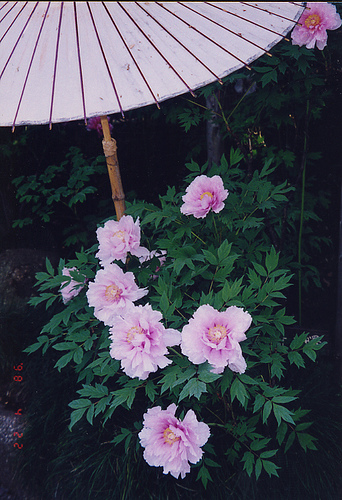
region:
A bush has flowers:
[49, 221, 336, 484]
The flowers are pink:
[54, 260, 292, 375]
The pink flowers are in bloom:
[55, 308, 321, 476]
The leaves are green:
[19, 319, 306, 496]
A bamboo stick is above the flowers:
[92, 120, 193, 233]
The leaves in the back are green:
[13, 140, 122, 217]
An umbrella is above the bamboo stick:
[0, 5, 215, 199]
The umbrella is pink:
[1, 359, 37, 451]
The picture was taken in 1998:
[7, 358, 48, 468]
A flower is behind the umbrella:
[255, 5, 340, 25]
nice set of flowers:
[39, 240, 253, 389]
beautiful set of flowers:
[39, 277, 285, 468]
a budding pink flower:
[128, 399, 215, 482]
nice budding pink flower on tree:
[129, 403, 213, 483]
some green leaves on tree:
[222, 393, 286, 473]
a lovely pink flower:
[134, 396, 212, 484]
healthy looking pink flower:
[127, 399, 213, 483]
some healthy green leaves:
[224, 379, 307, 447]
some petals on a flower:
[181, 416, 212, 459]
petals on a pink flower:
[140, 409, 163, 464]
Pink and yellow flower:
[172, 165, 241, 226]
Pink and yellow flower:
[187, 312, 248, 378]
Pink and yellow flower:
[117, 390, 216, 490]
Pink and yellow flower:
[96, 313, 179, 390]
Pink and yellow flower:
[86, 261, 150, 317]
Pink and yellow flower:
[90, 219, 170, 277]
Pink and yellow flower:
[136, 238, 169, 293]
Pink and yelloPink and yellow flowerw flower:
[50, 259, 106, 335]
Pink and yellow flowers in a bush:
[42, 181, 267, 454]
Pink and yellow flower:
[291, 6, 341, 66]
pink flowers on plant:
[51, 182, 270, 491]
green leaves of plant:
[40, 163, 317, 478]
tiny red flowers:
[8, 358, 27, 456]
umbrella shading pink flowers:
[6, 0, 318, 147]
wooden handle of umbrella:
[97, 125, 136, 217]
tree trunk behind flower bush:
[199, 92, 226, 162]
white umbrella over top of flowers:
[1, 3, 301, 123]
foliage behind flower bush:
[17, 136, 340, 267]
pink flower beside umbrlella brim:
[290, 5, 336, 46]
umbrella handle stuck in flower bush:
[97, 128, 133, 225]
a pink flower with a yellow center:
[178, 175, 230, 220]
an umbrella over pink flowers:
[1, 2, 314, 185]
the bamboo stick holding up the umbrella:
[96, 123, 131, 216]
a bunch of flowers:
[93, 216, 270, 397]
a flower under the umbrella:
[84, 115, 119, 139]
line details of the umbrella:
[1, 1, 314, 131]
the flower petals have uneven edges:
[163, 449, 194, 480]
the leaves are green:
[243, 440, 280, 481]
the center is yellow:
[204, 322, 231, 341]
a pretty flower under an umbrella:
[181, 175, 238, 223]